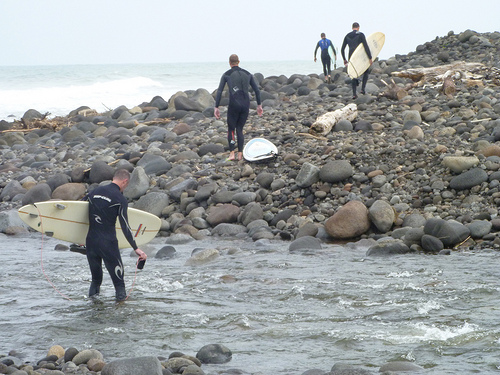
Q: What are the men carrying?
A: Surf boards.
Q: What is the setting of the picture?
A: A rocky beach.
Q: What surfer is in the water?
A: The one in the black wet suit carrying the surf board and looking down.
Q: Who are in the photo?
A: Surfers.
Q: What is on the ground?
A: Rocks.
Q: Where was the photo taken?
A: Waterbody.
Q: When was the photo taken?
A: Daytime.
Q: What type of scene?
A: Outdoor.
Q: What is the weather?
A: Sunny.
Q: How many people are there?
A: Four.